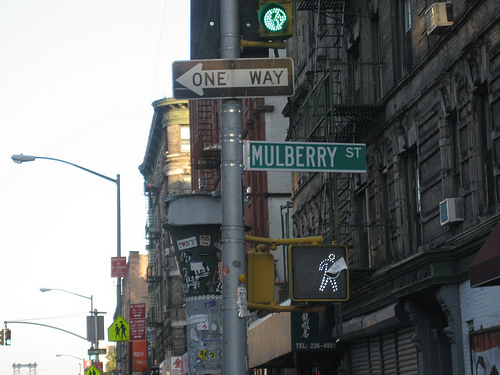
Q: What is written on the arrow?
A: One way.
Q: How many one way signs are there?
A: One.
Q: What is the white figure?
A: Pedestrian.